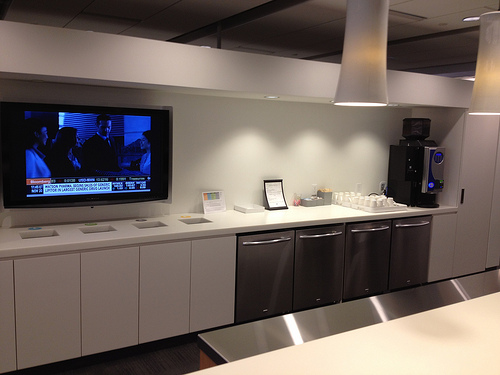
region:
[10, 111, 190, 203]
television is turned on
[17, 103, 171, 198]
black border around television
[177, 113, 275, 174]
wall near tv is white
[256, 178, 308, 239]
black picture frame near wall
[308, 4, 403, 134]
white lamp hanging from ceiling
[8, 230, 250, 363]
white cabinets under television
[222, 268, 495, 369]
steel counter across from television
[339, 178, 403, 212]
white paper cups on counter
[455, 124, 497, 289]
white door near coffee dispenser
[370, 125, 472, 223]
coffee dispenser is black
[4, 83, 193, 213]
flatscreen television on wall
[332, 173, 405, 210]
upside down paper cups stacked in rows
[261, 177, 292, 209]
piece of paper framed in black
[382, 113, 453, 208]
black electric beverage dispenser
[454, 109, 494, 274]
plain white door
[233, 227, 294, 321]
dark grey steel cupboard door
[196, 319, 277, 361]
edge of steel tabletop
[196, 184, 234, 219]
writing on white paper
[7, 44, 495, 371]
kitchen lounge area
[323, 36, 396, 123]
round hanging light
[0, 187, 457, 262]
THE COUNTER IS WHITE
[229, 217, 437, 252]
THE HANDLES ARE SILVER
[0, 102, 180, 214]
THE TELEFISION IS ON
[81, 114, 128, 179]
THE MAN IS ON THE TELEVISION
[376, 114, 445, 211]
THE BEVERAGE MACHINE IS BLACK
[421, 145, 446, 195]
THE MACHINE HAS BLUE LIGHTS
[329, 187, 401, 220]
MANY CUPS ON THE COUNTER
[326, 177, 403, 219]
THE CUPS ARE WHITE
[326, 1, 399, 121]
THIS IS A LIGHT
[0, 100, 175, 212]
THIS IS A TELEVISION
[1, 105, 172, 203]
A TV is on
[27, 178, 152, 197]
Information on bottom of TV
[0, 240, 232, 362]
The counter is white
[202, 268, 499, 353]
The surface is metal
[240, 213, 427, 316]
Cabinets made of metal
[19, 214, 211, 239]
Depressions in the surface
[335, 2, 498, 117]
Lights on the ceiling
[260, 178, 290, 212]
A paper leans against the wall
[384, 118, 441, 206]
A large coffee machine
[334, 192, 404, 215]
White paper cups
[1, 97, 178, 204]
the tv in the wall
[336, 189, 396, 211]
the white cups on a tray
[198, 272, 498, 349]
the silver counter top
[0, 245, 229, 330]
the white cabinets under the tv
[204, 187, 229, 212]
the paper closest to the tv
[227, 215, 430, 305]
the four silver appliances under the cabinet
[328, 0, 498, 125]
the lights hanging from the ceiling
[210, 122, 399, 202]
the light shining on the wall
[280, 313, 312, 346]
the light reflected onto the stainless steel countertop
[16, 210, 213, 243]
the four holes in the white countertop